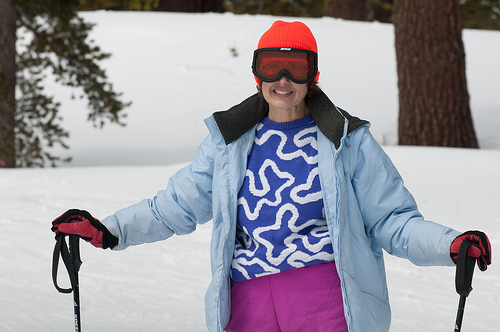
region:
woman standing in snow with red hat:
[46, 17, 486, 327]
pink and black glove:
[38, 203, 127, 252]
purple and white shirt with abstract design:
[230, 118, 341, 275]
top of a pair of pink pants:
[220, 272, 373, 328]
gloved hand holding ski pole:
[46, 212, 97, 329]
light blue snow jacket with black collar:
[101, 93, 461, 322]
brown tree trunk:
[386, 2, 490, 152]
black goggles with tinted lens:
[247, 43, 321, 82]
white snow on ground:
[6, 136, 493, 327]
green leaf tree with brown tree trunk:
[1, 1, 127, 191]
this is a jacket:
[56, 87, 483, 325]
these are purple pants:
[206, 250, 362, 330]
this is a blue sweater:
[208, 103, 360, 278]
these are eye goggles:
[241, 45, 335, 98]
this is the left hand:
[442, 220, 496, 272]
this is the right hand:
[22, 191, 142, 259]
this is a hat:
[243, 17, 351, 95]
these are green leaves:
[28, 27, 128, 97]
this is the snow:
[130, 290, 170, 317]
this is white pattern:
[250, 157, 312, 237]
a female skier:
[42, 19, 497, 327]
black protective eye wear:
[242, 49, 324, 88]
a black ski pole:
[44, 227, 95, 327]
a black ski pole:
[447, 249, 479, 329]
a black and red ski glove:
[41, 199, 127, 258]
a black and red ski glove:
[452, 225, 490, 275]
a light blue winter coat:
[96, 79, 461, 330]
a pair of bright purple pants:
[223, 266, 343, 330]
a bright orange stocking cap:
[249, 17, 320, 61]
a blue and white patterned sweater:
[218, 121, 333, 283]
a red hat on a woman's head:
[245, 22, 327, 66]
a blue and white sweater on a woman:
[224, 124, 351, 291]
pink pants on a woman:
[224, 251, 354, 329]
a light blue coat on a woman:
[94, 98, 445, 327]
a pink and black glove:
[50, 205, 121, 250]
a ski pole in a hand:
[447, 232, 487, 330]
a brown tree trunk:
[384, 0, 474, 150]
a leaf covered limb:
[18, 7, 141, 127]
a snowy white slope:
[4, 147, 498, 329]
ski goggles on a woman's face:
[244, 49, 330, 80]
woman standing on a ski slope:
[43, 10, 498, 329]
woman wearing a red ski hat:
[46, 8, 411, 328]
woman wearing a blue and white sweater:
[68, 3, 488, 313]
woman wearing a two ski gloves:
[34, 12, 496, 321]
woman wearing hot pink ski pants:
[66, 7, 493, 328]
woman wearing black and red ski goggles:
[33, 15, 498, 320]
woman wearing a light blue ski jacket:
[62, 8, 492, 329]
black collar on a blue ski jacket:
[211, 74, 371, 195]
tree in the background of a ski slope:
[3, 1, 168, 165]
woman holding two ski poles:
[41, 3, 494, 325]